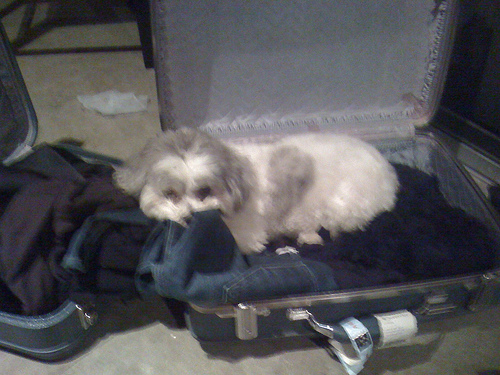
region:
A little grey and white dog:
[113, 125, 403, 260]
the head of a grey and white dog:
[115, 125, 250, 222]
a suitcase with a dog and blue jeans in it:
[150, 19, 494, 346]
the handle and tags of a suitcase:
[285, 300, 440, 374]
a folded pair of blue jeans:
[135, 220, 346, 308]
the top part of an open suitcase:
[148, 4, 455, 146]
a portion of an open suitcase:
[6, 98, 136, 365]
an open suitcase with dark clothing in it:
[3, 28, 152, 369]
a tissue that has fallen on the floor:
[73, 83, 153, 123]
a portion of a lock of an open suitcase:
[214, 300, 278, 342]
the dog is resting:
[120, 125, 396, 250]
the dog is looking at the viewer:
[125, 133, 241, 220]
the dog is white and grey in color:
[115, 126, 397, 254]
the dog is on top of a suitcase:
[120, 123, 397, 255]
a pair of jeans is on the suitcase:
[66, 192, 335, 307]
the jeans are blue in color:
[66, 200, 328, 312]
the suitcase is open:
[137, 3, 495, 351]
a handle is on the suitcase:
[292, 295, 440, 347]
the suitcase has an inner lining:
[162, 13, 447, 147]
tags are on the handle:
[341, 308, 416, 373]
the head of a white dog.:
[104, 123, 253, 237]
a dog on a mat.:
[214, 125, 409, 255]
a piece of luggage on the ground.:
[146, 113, 498, 367]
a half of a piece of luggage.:
[0, 128, 170, 357]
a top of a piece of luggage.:
[221, 272, 468, 374]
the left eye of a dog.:
[189, 180, 219, 209]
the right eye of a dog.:
[157, 173, 194, 210]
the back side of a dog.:
[310, 126, 398, 246]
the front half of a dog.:
[211, 128, 286, 260]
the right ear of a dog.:
[110, 123, 155, 199]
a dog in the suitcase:
[93, 109, 452, 285]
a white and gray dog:
[94, 108, 415, 259]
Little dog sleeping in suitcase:
[117, 120, 401, 257]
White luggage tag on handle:
[371, 312, 421, 348]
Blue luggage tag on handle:
[326, 315, 374, 374]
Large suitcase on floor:
[142, 2, 499, 356]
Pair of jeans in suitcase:
[142, 223, 337, 303]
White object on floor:
[68, 82, 153, 119]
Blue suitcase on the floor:
[0, 12, 141, 365]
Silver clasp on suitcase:
[220, 304, 272, 340]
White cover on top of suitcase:
[162, 4, 447, 126]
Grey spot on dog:
[264, 140, 317, 230]